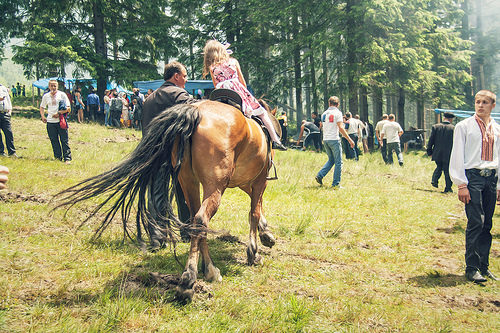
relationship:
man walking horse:
[447, 88, 500, 280] [164, 82, 313, 289]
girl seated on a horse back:
[200, 38, 291, 152] [200, 90, 283, 182]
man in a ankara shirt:
[447, 88, 500, 280] [39, 90, 75, 130]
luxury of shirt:
[453, 121, 497, 175] [450, 121, 485, 162]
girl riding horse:
[200, 38, 291, 152] [172, 158, 270, 202]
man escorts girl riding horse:
[154, 77, 190, 130] [154, 112, 264, 210]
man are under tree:
[447, 88, 500, 280] [71, 100, 133, 153]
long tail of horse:
[41, 102, 222, 255] [192, 113, 268, 199]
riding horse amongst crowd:
[12, 60, 498, 333] [250, 99, 431, 219]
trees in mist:
[254, 55, 454, 84] [290, 104, 417, 176]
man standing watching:
[447, 88, 500, 280] [44, 100, 53, 107]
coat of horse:
[202, 106, 283, 166] [211, 147, 240, 175]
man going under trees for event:
[447, 88, 500, 280] [282, 101, 390, 130]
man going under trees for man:
[447, 88, 500, 280] [447, 88, 500, 280]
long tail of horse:
[41, 102, 222, 255] [182, 141, 254, 210]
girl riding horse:
[200, 38, 291, 152] [156, 125, 284, 225]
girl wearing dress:
[200, 38, 291, 152] [224, 99, 264, 100]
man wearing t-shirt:
[447, 88, 500, 280] [32, 105, 63, 120]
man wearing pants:
[447, 88, 500, 280] [44, 149, 74, 171]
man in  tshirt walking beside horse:
[447, 88, 500, 280] [191, 164, 248, 192]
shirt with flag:
[319, 105, 342, 141] [319, 113, 334, 123]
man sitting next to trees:
[447, 88, 500, 280] [2, 22, 204, 87]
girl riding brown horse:
[202, 35, 291, 151] [40, 99, 276, 304]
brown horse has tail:
[40, 99, 276, 304] [47, 102, 197, 264]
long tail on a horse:
[108, 85, 260, 248] [169, 81, 300, 242]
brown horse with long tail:
[118, 109, 345, 329] [41, 102, 222, 255]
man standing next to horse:
[447, 88, 500, 280] [164, 115, 304, 280]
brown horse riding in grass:
[40, 99, 276, 304] [373, 237, 408, 304]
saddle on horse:
[198, 70, 275, 135] [169, 95, 329, 304]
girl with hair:
[200, 38, 291, 152] [200, 39, 231, 81]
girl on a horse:
[200, 38, 291, 152] [193, 104, 305, 242]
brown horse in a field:
[40, 99, 276, 304] [315, 197, 392, 330]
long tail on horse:
[41, 102, 222, 255] [181, 106, 278, 274]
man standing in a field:
[447, 88, 500, 280] [0, 114, 498, 329]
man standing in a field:
[38, 77, 71, 166] [0, 114, 498, 329]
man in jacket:
[447, 88, 500, 280] [425, 120, 454, 160]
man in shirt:
[447, 88, 500, 280] [301, 121, 321, 133]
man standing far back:
[447, 88, 500, 280] [1, 1, 484, 113]